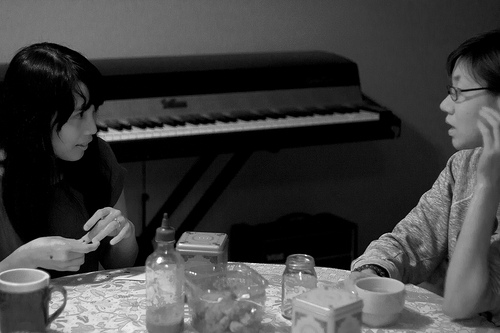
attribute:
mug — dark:
[5, 263, 72, 325]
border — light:
[4, 260, 51, 291]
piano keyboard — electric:
[72, 48, 405, 163]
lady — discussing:
[337, 35, 499, 322]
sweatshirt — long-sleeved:
[359, 148, 497, 325]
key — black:
[167, 115, 179, 130]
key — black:
[318, 108, 327, 125]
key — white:
[271, 111, 284, 131]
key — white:
[342, 106, 352, 126]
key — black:
[188, 113, 204, 137]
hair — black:
[2, 13, 117, 181]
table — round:
[35, 227, 485, 331]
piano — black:
[67, 35, 399, 167]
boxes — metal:
[141, 217, 292, 295]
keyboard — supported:
[122, 116, 367, 147]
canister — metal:
[277, 250, 331, 302]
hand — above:
[466, 104, 497, 156]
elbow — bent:
[441, 262, 489, 332]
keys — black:
[101, 87, 435, 158]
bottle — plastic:
[145, 212, 184, 329]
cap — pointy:
[155, 212, 172, 239]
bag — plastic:
[183, 260, 270, 331]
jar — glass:
[145, 212, 185, 332]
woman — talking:
[347, 32, 498, 326]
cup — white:
[346, 274, 407, 328]